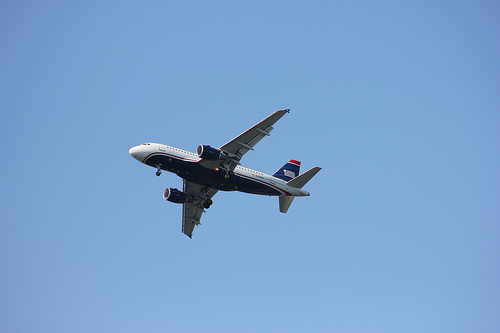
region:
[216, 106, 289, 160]
wing of a plane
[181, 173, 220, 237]
wing of a plane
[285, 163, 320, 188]
tail wing of plane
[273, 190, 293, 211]
tail wing of plane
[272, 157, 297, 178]
tail wing of plane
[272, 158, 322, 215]
tail wings of plane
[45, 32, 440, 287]
airplane flying under clear blue sky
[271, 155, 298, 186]
red, white and blue tail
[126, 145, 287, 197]
red stripe around underside of plane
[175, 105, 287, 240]
grey triangular shape of wings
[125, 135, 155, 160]
pointed nose on front of plane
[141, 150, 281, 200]
dark underside of plane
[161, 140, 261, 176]
row of passenger windows on side of plane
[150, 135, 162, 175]
black wheel hanging under plane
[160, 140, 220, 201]
round engines in front of both wings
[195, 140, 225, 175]
bright white light below engine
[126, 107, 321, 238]
airplane is red, white and blue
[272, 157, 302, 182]
airplane has a tail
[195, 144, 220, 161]
blue and white engine on airplane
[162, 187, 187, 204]
blue and white engine on the airplane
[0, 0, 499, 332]
sky is clear and blue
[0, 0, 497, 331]
airplane in the sky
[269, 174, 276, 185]
white door on the airplane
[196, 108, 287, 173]
white wing on the airplane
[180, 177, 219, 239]
white wing on the airplane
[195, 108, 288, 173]
blue and white engine on airplane wing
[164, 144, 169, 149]
small window on plane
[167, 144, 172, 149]
small window on plane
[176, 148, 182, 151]
small window on plane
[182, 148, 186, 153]
small window on plane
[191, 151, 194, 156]
small window on plane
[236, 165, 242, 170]
small window on plane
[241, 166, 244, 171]
small window on plane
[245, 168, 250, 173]
small window on plane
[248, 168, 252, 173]
small window on plane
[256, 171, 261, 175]
small window on plane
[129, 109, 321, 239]
A white, blue and red plane.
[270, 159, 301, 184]
Red, white and blue tail end of a plane.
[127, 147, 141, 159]
White nose of a plane.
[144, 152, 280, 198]
Blue underbody of a plane.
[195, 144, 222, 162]
Engine to the right of another.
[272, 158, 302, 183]
Blue, white and red tail end of a plane.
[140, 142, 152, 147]
Two front side plane windows.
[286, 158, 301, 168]
Red stripe on the tail end of a plane.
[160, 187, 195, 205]
Engine on the other side of the plane.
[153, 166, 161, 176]
Two black front wheels.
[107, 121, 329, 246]
A plane in the air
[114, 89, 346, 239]
A plane flying in the skies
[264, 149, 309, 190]
A tail of a plane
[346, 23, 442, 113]
Blue clear skies